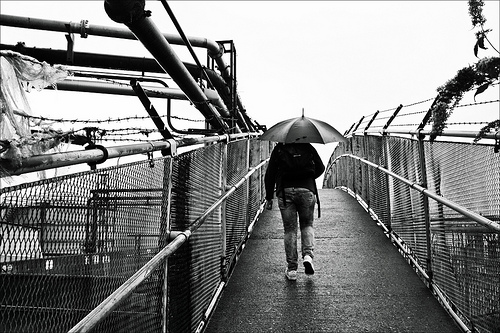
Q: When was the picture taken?
A: Daytime.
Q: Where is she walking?
A: Bridge.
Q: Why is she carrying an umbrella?
A: Rain.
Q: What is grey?
A: Sky.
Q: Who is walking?
A: Woman.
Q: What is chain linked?
A: Fence.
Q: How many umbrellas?
A: One.